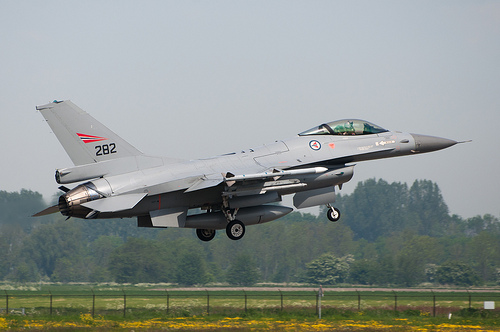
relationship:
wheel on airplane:
[194, 227, 216, 240] [28, 98, 475, 242]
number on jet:
[109, 142, 117, 154] [26, 104, 477, 281]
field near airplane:
[79, 310, 199, 321] [60, 152, 376, 230]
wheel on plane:
[324, 200, 345, 221] [31, 85, 474, 240]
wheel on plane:
[225, 217, 247, 241] [31, 85, 474, 240]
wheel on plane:
[194, 227, 216, 241] [31, 85, 474, 240]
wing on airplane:
[23, 87, 164, 180] [28, 98, 475, 242]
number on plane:
[83, 137, 127, 161] [31, 85, 474, 240]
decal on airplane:
[300, 138, 329, 152] [28, 98, 475, 242]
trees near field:
[428, 214, 470, 277] [1, 263, 499, 331]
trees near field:
[347, 177, 420, 242] [0, 268, 497, 328]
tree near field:
[220, 251, 268, 290] [0, 268, 497, 328]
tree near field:
[166, 235, 218, 290] [0, 277, 499, 330]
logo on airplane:
[71, 125, 114, 150] [28, 98, 475, 242]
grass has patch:
[0, 283, 499, 330] [126, 316, 173, 328]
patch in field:
[126, 316, 173, 328] [1, 279, 496, 325]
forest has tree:
[2, 149, 495, 289] [21, 216, 69, 271]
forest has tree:
[2, 149, 495, 289] [76, 226, 131, 274]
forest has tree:
[2, 149, 495, 289] [351, 173, 420, 244]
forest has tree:
[2, 149, 495, 289] [410, 176, 450, 242]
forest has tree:
[2, 149, 495, 289] [350, 238, 399, 283]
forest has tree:
[2, 149, 495, 289] [235, 218, 275, 277]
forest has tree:
[2, 149, 495, 289] [290, 219, 323, 272]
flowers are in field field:
[91, 308, 179, 328] [0, 277, 499, 330]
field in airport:
[0, 277, 499, 330] [6, 6, 482, 316]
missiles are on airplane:
[191, 203, 291, 224] [28, 98, 475, 242]